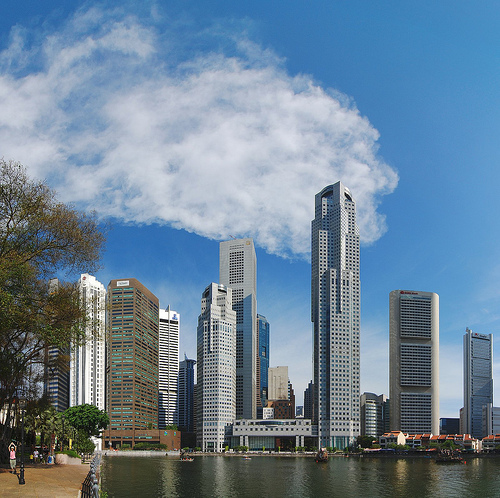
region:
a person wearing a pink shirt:
[2, 430, 19, 476]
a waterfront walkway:
[97, 418, 498, 496]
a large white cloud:
[1, 0, 375, 260]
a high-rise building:
[307, 182, 362, 452]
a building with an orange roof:
[375, 426, 498, 463]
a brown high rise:
[110, 273, 160, 455]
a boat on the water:
[174, 450, 198, 465]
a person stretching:
[4, 440, 19, 475]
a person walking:
[0, 437, 18, 479]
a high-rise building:
[388, 284, 438, 441]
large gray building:
[302, 179, 364, 426]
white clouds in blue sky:
[6, 7, 101, 77]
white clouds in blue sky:
[3, 77, 71, 131]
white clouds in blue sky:
[41, 130, 119, 185]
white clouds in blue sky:
[105, 24, 196, 112]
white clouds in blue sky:
[131, 113, 239, 193]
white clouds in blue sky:
[231, 14, 351, 91]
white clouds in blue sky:
[242, 71, 313, 151]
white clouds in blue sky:
[228, 164, 289, 219]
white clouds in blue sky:
[352, 29, 463, 116]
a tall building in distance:
[312, 177, 363, 452]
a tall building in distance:
[219, 237, 258, 416]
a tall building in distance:
[197, 281, 238, 451]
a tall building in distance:
[256, 311, 270, 416]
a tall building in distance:
[389, 285, 441, 435]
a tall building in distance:
[463, 330, 495, 435]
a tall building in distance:
[159, 306, 179, 428]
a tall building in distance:
[104, 278, 158, 428]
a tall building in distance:
[69, 271, 106, 406]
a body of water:
[99, 451, 496, 496]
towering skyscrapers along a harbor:
[10, 46, 495, 488]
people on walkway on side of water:
[5, 435, 110, 495]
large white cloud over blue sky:
[5, 10, 485, 280]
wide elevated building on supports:
[230, 415, 310, 450]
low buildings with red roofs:
[375, 430, 495, 450]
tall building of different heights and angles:
[307, 176, 358, 451]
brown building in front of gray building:
[105, 271, 177, 446]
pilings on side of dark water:
[85, 451, 487, 491]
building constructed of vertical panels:
[465, 326, 495, 436]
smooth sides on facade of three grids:
[386, 286, 439, 434]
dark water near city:
[101, 455, 499, 495]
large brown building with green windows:
[102, 278, 180, 450]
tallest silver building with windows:
[311, 180, 361, 452]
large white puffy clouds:
[1, 160, 398, 265]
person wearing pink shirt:
[8, 442, 16, 474]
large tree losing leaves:
[0, 154, 112, 466]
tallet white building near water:
[69, 273, 105, 450]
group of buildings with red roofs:
[379, 430, 498, 452]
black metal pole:
[19, 398, 25, 485]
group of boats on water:
[176, 448, 497, 462]